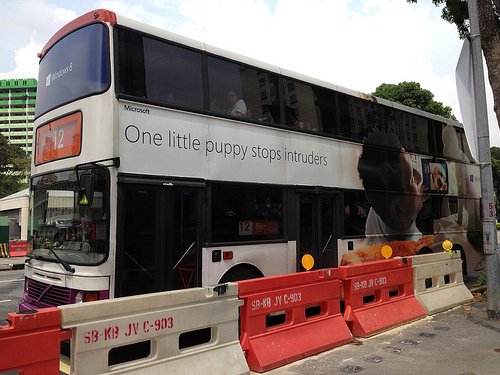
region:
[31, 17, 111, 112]
window on large bus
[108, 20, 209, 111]
window on large bus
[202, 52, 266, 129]
window on large bus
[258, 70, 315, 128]
window on large bus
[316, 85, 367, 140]
window on large bus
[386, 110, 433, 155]
window on large bus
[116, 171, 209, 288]
window on large bus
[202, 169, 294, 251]
window on large bus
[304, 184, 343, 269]
window on large bus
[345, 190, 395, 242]
window on large bus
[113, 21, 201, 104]
large tinted bus window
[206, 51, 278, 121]
large tinted bus window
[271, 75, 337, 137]
large tinted bus window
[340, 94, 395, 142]
large tinted bus window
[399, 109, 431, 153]
large tinted bus window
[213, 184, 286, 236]
large tinted bus window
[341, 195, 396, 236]
large tinted bus window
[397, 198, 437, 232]
large tinted bus window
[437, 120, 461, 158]
large tinted bus window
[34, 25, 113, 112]
large tinted bus window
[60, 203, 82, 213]
windshield of the bus.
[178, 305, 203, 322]
white barricade near bus.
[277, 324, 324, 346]
red barricade near bus.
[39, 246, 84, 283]
windshield wiper on bus.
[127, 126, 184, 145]
writing on the bus.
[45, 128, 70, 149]
number on the bus.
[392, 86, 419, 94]
leaves on the tree.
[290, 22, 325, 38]
clouds in the sky.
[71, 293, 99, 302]
headlights on the bus.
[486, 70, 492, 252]
pole on the sidewalk.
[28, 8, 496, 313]
double decker bus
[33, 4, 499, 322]
white bus parked on the street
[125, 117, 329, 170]
black lettering on white background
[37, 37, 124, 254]
front windshields on the bus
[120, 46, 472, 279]
windows on the side of the bus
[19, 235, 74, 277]
windshield wipers on front windshield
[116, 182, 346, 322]
two sets of doors on the bus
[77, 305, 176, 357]
red lettering on white background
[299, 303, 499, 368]
sidewalk next to bus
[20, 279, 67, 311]
purple grill on the front of the bus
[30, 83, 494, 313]
white double decker bus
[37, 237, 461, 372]
red and white barriers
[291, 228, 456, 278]
orange lights on barriers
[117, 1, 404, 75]
blue and white sky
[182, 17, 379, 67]
puffy and white clouds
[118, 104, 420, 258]
advert on side of bus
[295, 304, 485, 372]
light brown sidewalk near barriers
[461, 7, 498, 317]
grey pole on sidewalk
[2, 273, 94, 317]
purple grille on bus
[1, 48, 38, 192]
green building behind bus